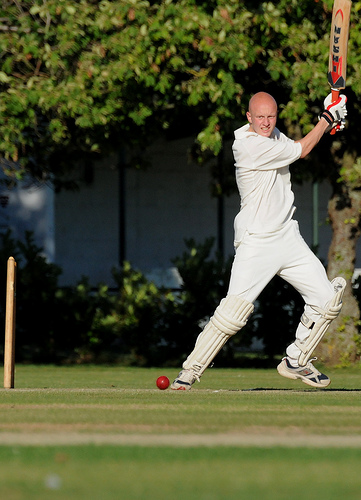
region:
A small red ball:
[154, 372, 170, 391]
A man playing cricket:
[165, 89, 347, 392]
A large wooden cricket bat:
[324, 0, 353, 136]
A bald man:
[170, 88, 347, 389]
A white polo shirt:
[231, 123, 302, 249]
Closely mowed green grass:
[0, 364, 359, 458]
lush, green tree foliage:
[2, 0, 360, 182]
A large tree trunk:
[307, 139, 359, 368]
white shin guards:
[181, 275, 347, 375]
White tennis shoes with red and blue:
[170, 356, 331, 391]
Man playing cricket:
[174, 19, 355, 401]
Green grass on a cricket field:
[51, 388, 329, 485]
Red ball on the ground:
[128, 369, 174, 404]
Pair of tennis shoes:
[156, 353, 339, 395]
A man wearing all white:
[206, 92, 344, 371]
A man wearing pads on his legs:
[177, 82, 347, 390]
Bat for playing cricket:
[315, 0, 354, 152]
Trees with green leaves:
[7, 2, 347, 153]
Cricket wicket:
[2, 244, 25, 395]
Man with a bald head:
[222, 87, 316, 174]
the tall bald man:
[171, 90, 346, 387]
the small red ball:
[157, 375, 169, 387]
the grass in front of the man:
[49, 389, 345, 431]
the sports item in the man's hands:
[325, 2, 352, 134]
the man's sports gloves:
[324, 93, 345, 131]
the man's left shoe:
[279, 355, 329, 386]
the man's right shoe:
[171, 369, 194, 390]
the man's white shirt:
[232, 124, 303, 225]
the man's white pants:
[163, 222, 338, 362]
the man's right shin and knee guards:
[190, 298, 251, 369]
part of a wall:
[161, 174, 193, 224]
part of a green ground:
[201, 437, 232, 476]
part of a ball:
[155, 370, 171, 396]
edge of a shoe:
[169, 370, 190, 392]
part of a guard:
[194, 354, 210, 385]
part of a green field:
[159, 439, 183, 470]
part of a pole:
[2, 355, 16, 379]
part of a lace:
[186, 363, 201, 386]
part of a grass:
[177, 457, 197, 488]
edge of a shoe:
[297, 374, 326, 390]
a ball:
[152, 373, 173, 390]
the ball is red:
[151, 373, 172, 391]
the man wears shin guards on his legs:
[174, 273, 349, 405]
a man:
[161, 86, 346, 385]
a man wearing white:
[170, 87, 352, 389]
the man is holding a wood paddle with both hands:
[168, 1, 357, 394]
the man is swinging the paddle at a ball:
[153, 2, 353, 398]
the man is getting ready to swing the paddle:
[135, 2, 357, 399]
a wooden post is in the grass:
[1, 251, 24, 393]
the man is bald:
[168, 88, 345, 392]